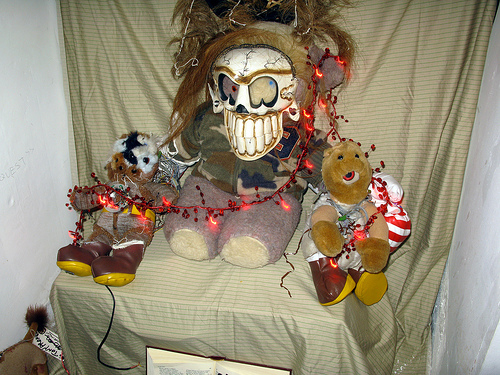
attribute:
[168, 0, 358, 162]
ugly mask — smiling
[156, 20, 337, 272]
bear — grey, beige, plush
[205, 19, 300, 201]
skull — white, decorated, painted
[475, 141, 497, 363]
wall — white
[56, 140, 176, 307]
bear — plush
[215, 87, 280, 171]
teeth — big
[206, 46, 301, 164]
mask — ugly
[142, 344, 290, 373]
book — propped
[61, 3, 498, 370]
sheet — beige, backdrop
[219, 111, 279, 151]
teeth — sbig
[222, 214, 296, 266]
leg — purple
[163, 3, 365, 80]
hair — crazy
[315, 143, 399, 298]
plush bear — decorated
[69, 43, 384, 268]
lights — red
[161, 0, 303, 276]
decorated bear — plush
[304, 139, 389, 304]
decorated bear — plush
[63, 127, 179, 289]
decorated bear — plush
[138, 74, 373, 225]
wiring — red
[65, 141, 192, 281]
bear —  teddy, at left 